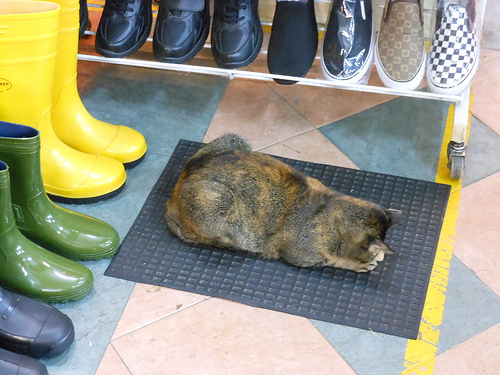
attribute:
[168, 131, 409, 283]
calico cat — black, orange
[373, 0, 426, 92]
shoe — checkered, brown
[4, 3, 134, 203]
boot — black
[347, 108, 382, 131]
tile — red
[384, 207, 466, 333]
mat — black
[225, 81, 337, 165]
tile — red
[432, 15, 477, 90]
checkered shoe — black, white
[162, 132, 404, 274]
cat — grey , black, brown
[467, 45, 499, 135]
tile — red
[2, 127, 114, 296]
green boots — olive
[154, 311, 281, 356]
tile — red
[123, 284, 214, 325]
tile — red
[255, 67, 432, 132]
tile — red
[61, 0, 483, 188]
rack — white